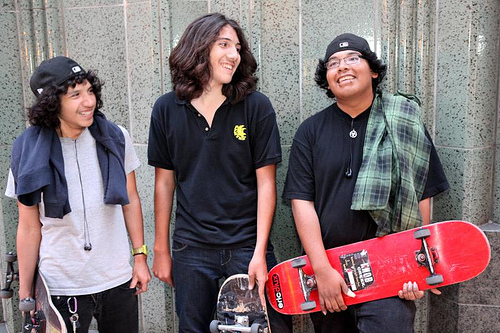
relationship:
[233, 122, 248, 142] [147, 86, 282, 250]
logo on front of shirt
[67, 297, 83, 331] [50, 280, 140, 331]
car keys on boys pants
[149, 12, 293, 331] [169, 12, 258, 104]
teen with long hair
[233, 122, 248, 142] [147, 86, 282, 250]
logo on black shirt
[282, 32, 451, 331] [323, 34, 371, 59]
boy wearing a backwards cap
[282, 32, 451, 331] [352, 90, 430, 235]
boy with green and black shirt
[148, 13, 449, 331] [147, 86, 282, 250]
boys in black shirt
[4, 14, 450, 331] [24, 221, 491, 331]
boys holding skateboards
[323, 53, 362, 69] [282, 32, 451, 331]
glasses on boy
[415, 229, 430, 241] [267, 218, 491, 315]
wheel of skateboard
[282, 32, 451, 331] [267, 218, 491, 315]
boy holding skateboard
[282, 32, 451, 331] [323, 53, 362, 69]
boy wearing glasses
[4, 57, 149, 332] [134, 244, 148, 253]
boy wearing a watch